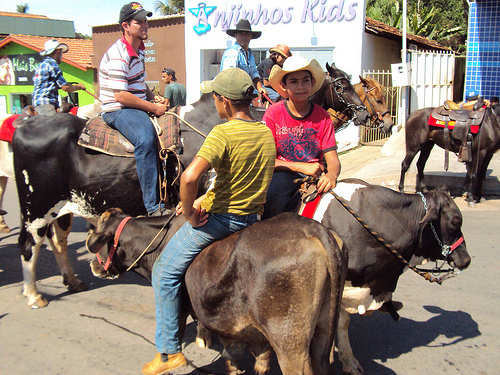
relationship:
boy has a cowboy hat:
[265, 50, 339, 221] [267, 52, 329, 99]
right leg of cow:
[17, 179, 61, 311] [13, 92, 224, 299]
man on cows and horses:
[98, 1, 171, 218] [13, 61, 499, 370]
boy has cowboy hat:
[265, 50, 339, 221] [267, 52, 329, 99]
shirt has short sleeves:
[202, 115, 277, 218] [196, 134, 227, 169]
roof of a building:
[0, 31, 96, 75] [2, 34, 101, 113]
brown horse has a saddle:
[396, 95, 496, 203] [430, 98, 486, 148]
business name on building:
[190, 2, 363, 38] [2, 34, 101, 113]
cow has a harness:
[13, 92, 224, 299] [81, 105, 183, 162]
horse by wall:
[396, 95, 496, 203] [459, 3, 500, 100]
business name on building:
[190, 2, 363, 38] [186, 4, 448, 141]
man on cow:
[99, 3, 170, 212] [13, 92, 224, 299]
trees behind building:
[370, 2, 469, 47] [186, 4, 448, 141]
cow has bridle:
[234, 177, 473, 365] [434, 231, 472, 276]